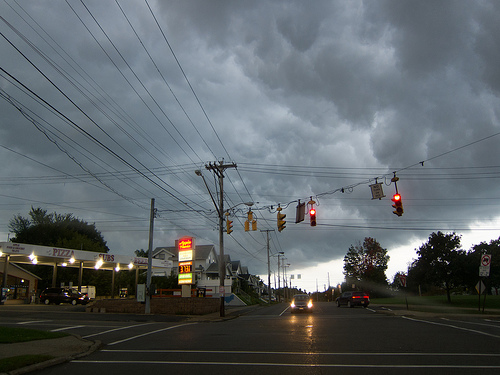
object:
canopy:
[0, 242, 174, 272]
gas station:
[0, 255, 175, 310]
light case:
[225, 220, 235, 234]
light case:
[277, 213, 287, 232]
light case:
[252, 220, 258, 231]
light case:
[245, 220, 251, 233]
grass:
[368, 294, 498, 306]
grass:
[0, 325, 69, 375]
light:
[289, 298, 296, 310]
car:
[290, 293, 314, 315]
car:
[334, 289, 371, 309]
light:
[352, 296, 360, 299]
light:
[362, 295, 369, 298]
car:
[39, 286, 92, 305]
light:
[78, 296, 84, 300]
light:
[308, 208, 317, 215]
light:
[393, 193, 401, 201]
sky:
[1, 0, 499, 294]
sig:
[178, 236, 193, 250]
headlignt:
[305, 299, 313, 309]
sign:
[178, 235, 195, 284]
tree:
[7, 204, 109, 256]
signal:
[389, 191, 406, 217]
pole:
[214, 168, 227, 318]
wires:
[145, 1, 286, 255]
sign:
[51, 246, 78, 259]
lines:
[99, 347, 500, 356]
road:
[1, 292, 500, 372]